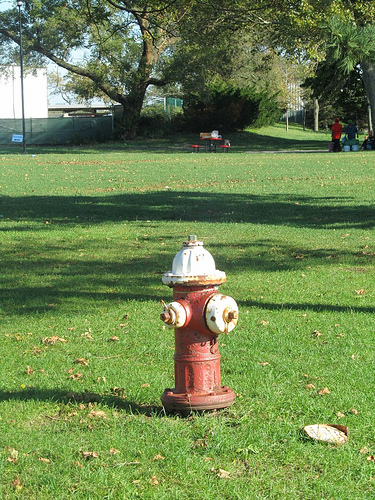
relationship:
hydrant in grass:
[160, 233, 240, 415] [4, 152, 373, 497]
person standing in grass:
[346, 113, 360, 143] [2, 126, 357, 498]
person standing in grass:
[329, 118, 343, 149] [2, 126, 357, 498]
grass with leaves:
[2, 126, 357, 498] [34, 189, 364, 495]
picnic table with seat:
[188, 136, 230, 153] [188, 143, 200, 147]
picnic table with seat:
[188, 136, 230, 153] [218, 144, 230, 149]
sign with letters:
[8, 124, 27, 151] [10, 130, 22, 138]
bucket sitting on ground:
[342, 144, 351, 152] [1, 121, 361, 498]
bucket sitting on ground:
[351, 143, 359, 151] [1, 121, 361, 498]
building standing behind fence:
[1, 63, 50, 133] [0, 96, 181, 145]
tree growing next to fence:
[1, 0, 324, 141] [0, 96, 181, 145]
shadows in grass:
[20, 176, 82, 292] [17, 295, 103, 402]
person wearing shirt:
[329, 118, 343, 149] [332, 122, 343, 140]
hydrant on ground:
[160, 233, 240, 415] [1, 121, 361, 498]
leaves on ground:
[9, 319, 161, 479] [1, 121, 361, 498]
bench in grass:
[191, 130, 233, 150] [2, 126, 357, 498]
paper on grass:
[302, 420, 353, 445] [2, 126, 357, 498]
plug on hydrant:
[204, 291, 242, 340] [160, 233, 240, 415]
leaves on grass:
[24, 320, 164, 456] [2, 126, 357, 498]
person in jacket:
[329, 118, 343, 149] [330, 123, 342, 140]